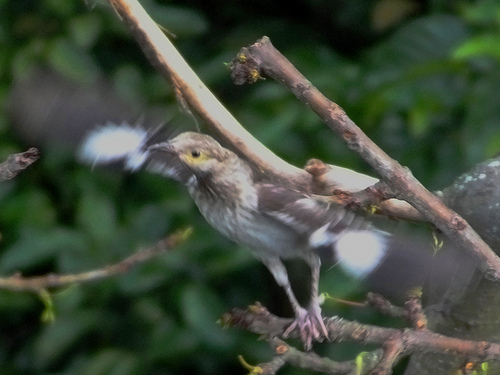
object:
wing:
[9, 79, 200, 186]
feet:
[284, 309, 312, 352]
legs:
[264, 253, 299, 305]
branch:
[235, 291, 499, 357]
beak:
[148, 140, 175, 157]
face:
[174, 137, 210, 169]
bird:
[148, 130, 404, 353]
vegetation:
[3, 5, 498, 375]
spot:
[80, 118, 149, 171]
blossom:
[234, 354, 267, 374]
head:
[146, 130, 220, 179]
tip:
[213, 299, 267, 328]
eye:
[190, 150, 201, 158]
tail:
[332, 202, 398, 239]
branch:
[236, 32, 500, 278]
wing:
[254, 181, 481, 305]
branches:
[113, 6, 500, 228]